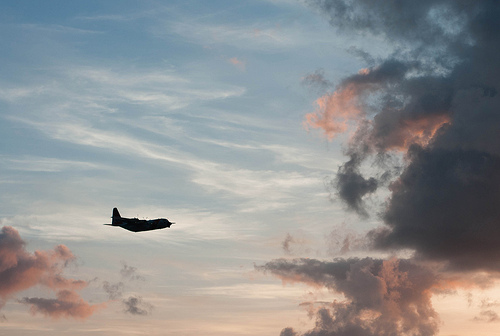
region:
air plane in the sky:
[84, 196, 214, 251]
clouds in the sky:
[316, 8, 496, 327]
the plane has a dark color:
[107, 201, 178, 237]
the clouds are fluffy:
[345, 127, 450, 334]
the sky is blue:
[2, 2, 292, 94]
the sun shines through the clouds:
[380, 104, 446, 156]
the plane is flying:
[104, 206, 214, 238]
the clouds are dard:
[445, 107, 497, 274]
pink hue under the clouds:
[427, 274, 497, 334]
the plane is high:
[90, 190, 215, 287]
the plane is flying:
[87, 190, 205, 256]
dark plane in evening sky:
[105, 202, 177, 237]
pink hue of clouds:
[300, 79, 371, 150]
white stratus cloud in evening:
[35, 55, 301, 208]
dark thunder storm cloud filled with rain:
[386, 76, 498, 292]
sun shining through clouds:
[419, 265, 496, 325]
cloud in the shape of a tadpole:
[305, 53, 412, 143]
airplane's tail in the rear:
[105, 199, 122, 230]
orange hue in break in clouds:
[397, 108, 457, 158]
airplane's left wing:
[163, 217, 178, 231]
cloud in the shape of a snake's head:
[328, 121, 386, 233]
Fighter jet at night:
[79, 198, 175, 235]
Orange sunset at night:
[1, 223, 114, 328]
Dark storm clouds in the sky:
[417, 82, 498, 235]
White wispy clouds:
[42, 44, 260, 167]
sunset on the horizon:
[2, 293, 494, 333]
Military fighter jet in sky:
[87, 204, 183, 239]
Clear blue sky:
[29, 18, 125, 54]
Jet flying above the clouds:
[94, 204, 194, 240]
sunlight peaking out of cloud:
[402, 115, 459, 157]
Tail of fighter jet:
[107, 199, 124, 231]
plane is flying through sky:
[94, 193, 183, 238]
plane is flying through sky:
[103, 197, 205, 262]